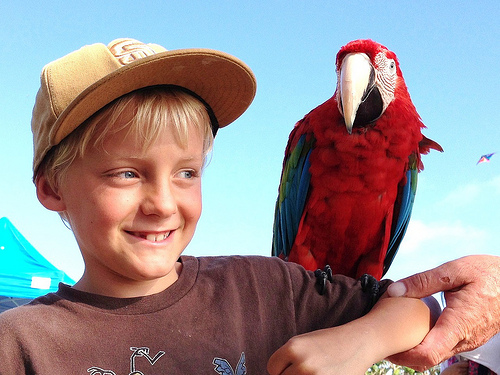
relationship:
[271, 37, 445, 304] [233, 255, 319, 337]
parrot sitting on shoulder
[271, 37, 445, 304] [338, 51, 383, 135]
parrot has beak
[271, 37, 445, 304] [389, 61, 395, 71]
parrot has eye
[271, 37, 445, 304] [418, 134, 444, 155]
parrot has feather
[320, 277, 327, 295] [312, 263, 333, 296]
talon on end of foot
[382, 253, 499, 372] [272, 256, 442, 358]
hand holding arm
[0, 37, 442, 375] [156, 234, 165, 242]
kid has front tooth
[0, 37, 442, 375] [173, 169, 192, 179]
kid has eye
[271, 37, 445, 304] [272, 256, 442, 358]
parrot sitting on arm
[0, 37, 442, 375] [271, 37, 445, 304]
kid has parrot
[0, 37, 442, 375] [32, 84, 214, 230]
kid has hair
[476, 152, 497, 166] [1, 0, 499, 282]
kite flying in sky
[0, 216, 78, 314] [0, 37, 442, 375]
tent behind kid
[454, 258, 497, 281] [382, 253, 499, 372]
cut on surface of hand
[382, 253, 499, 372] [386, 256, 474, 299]
hand has thumb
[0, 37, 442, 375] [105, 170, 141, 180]
kid has eye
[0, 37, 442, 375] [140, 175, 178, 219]
kid has nose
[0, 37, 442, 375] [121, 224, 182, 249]
kid has mouth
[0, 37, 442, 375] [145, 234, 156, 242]
kid has front tooth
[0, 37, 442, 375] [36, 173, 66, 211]
kid has left ear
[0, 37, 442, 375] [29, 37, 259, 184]
kid wearing baseball cap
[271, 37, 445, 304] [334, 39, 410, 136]
parrot has head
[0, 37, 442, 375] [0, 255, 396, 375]
kid wearing shirt